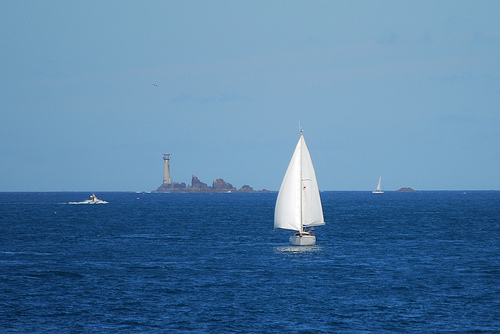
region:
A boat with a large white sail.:
[274, 133, 326, 245]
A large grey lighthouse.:
[162, 150, 170, 185]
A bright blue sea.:
[1, 188, 498, 331]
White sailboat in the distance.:
[373, 174, 385, 194]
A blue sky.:
[1, 1, 499, 190]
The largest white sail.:
[272, 133, 326, 229]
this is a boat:
[255, 126, 343, 256]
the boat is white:
[283, 228, 316, 248]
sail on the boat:
[269, 119, 337, 239]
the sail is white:
[263, 109, 328, 234]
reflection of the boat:
[273, 237, 321, 259]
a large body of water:
[10, 165, 458, 329]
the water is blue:
[0, 180, 498, 331]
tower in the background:
[158, 146, 180, 187]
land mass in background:
[142, 143, 254, 200]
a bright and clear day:
[9, 10, 496, 314]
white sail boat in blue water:
[270, 118, 329, 252]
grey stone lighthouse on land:
[148, 145, 184, 192]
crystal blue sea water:
[5, 176, 499, 329]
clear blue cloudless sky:
[6, 3, 498, 193]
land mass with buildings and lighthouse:
[150, 148, 273, 192]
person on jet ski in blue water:
[88, 194, 105, 204]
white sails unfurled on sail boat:
[270, 129, 328, 230]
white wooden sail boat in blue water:
[284, 230, 321, 248]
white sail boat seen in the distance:
[371, 177, 384, 197]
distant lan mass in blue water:
[398, 183, 413, 190]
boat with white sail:
[258, 119, 330, 271]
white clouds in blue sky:
[364, 23, 421, 88]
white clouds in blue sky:
[100, 53, 142, 87]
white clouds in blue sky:
[94, 11, 235, 81]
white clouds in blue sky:
[44, 112, 88, 134]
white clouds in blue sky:
[368, 91, 426, 136]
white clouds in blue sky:
[447, 39, 497, 110]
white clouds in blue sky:
[78, 61, 180, 99]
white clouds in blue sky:
[201, 112, 252, 163]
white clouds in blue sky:
[77, 58, 138, 93]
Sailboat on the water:
[271, 128, 326, 248]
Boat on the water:
[77, 193, 104, 203]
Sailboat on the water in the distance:
[370, 175, 386, 196]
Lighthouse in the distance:
[159, 145, 173, 190]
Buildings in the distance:
[187, 174, 253, 197]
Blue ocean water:
[2, 193, 497, 327]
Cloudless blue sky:
[1, 30, 497, 187]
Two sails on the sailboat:
[276, 129, 324, 234]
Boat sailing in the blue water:
[273, 124, 325, 248]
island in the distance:
[155, 148, 281, 198]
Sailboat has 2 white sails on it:
[271, 128, 331, 248]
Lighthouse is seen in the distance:
[152, 150, 179, 191]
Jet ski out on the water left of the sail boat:
[65, 189, 116, 209]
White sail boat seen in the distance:
[370, 175, 390, 201]